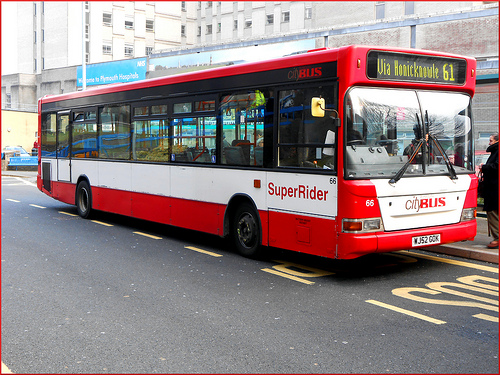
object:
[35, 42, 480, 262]
bus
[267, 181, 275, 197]
printing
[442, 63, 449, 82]
number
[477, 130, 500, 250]
person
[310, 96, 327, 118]
mirror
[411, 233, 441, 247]
plate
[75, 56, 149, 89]
sign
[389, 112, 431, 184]
wipers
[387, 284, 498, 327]
letters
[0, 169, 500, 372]
street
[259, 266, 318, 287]
lines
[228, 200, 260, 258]
tires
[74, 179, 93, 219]
tire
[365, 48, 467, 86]
sign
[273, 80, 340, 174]
window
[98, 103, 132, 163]
window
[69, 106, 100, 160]
window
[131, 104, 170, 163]
window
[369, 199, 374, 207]
numbers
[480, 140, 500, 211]
coat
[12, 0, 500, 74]
building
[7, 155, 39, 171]
bench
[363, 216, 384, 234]
lights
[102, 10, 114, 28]
windows